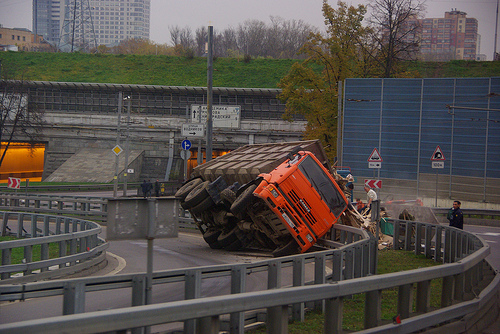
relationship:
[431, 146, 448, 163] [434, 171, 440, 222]
sign has post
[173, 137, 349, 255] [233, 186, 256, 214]
truck has wheel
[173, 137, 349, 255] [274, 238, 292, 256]
truck has wheel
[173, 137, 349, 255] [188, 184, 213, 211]
truck has wheel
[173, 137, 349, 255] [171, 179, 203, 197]
truck has wheel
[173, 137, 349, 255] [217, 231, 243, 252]
truck has wheel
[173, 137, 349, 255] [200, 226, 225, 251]
truck has wheel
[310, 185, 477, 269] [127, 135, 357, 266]
goods are from truck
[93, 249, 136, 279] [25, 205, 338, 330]
lines on road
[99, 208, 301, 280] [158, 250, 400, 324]
road way with rails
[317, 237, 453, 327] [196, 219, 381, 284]
grass between guard rails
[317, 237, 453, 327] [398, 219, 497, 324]
grass between guard rails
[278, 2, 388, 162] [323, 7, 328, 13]
tree has leaf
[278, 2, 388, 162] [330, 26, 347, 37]
tree has leaf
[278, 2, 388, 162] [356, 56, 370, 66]
tree has leaf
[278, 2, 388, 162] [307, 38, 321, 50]
tree has leaf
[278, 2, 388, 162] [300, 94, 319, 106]
tree has leaf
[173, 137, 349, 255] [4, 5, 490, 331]
truck in photo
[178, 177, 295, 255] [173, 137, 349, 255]
tires in truck